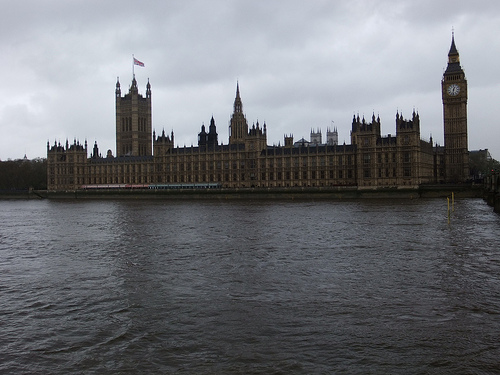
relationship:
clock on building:
[445, 82, 464, 99] [9, 30, 489, 225]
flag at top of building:
[127, 50, 144, 69] [38, 27, 498, 198]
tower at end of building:
[438, 17, 473, 149] [4, 108, 498, 190]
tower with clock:
[387, 17, 499, 199] [445, 65, 477, 122]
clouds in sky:
[1, 0, 498, 160] [1, 2, 499, 159]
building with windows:
[47, 111, 387, 201] [263, 166, 354, 185]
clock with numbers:
[443, 79, 463, 99] [447, 84, 458, 100]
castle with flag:
[36, 51, 251, 203] [113, 48, 149, 68]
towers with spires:
[308, 128, 338, 145] [350, 106, 383, 133]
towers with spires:
[348, 106, 423, 192] [393, 108, 418, 138]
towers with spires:
[114, 54, 153, 155] [308, 127, 320, 143]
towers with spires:
[193, 78, 266, 144] [325, 123, 340, 143]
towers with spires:
[45, 131, 89, 194] [150, 126, 173, 156]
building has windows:
[43, 111, 438, 197] [261, 149, 353, 185]